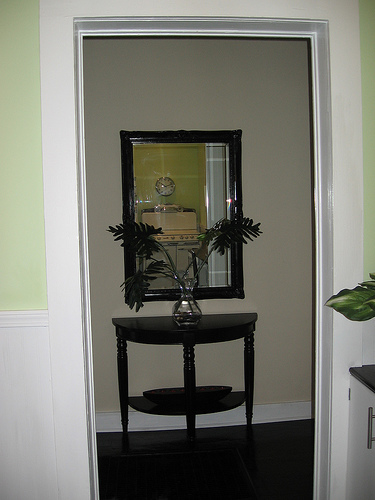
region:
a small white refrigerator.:
[343, 360, 374, 498]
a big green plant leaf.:
[323, 266, 374, 330]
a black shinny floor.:
[270, 440, 303, 483]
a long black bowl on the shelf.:
[140, 379, 237, 407]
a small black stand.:
[112, 310, 262, 453]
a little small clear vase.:
[166, 292, 212, 330]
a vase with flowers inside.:
[104, 202, 267, 327]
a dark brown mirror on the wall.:
[112, 117, 254, 308]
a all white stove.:
[138, 205, 207, 291]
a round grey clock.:
[145, 169, 184, 199]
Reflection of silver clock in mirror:
[154, 173, 178, 197]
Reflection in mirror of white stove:
[157, 204, 198, 253]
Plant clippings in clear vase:
[105, 218, 262, 327]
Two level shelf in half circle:
[111, 310, 258, 452]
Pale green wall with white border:
[6, 184, 46, 331]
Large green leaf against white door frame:
[318, 280, 371, 329]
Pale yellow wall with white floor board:
[259, 126, 310, 420]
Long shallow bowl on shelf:
[144, 383, 233, 409]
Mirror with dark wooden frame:
[114, 128, 248, 222]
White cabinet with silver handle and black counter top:
[344, 359, 374, 451]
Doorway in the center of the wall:
[69, 13, 337, 498]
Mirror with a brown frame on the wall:
[115, 127, 246, 305]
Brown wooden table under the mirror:
[109, 308, 262, 437]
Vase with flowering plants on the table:
[105, 213, 264, 329]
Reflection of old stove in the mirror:
[137, 203, 202, 294]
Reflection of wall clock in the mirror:
[150, 172, 177, 198]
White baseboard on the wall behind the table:
[94, 397, 316, 436]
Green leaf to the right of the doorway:
[323, 254, 373, 330]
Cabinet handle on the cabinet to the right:
[356, 405, 373, 456]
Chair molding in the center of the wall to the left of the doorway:
[0, 305, 51, 330]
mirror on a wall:
[110, 107, 260, 210]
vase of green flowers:
[100, 214, 250, 334]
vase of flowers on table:
[109, 210, 254, 315]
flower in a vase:
[198, 208, 260, 269]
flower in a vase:
[105, 215, 165, 251]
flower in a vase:
[120, 256, 150, 319]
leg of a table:
[226, 332, 260, 437]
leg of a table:
[178, 340, 211, 460]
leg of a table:
[111, 323, 130, 450]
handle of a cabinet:
[362, 399, 374, 454]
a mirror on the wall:
[104, 112, 255, 316]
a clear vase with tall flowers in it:
[126, 197, 256, 347]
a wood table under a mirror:
[96, 308, 266, 453]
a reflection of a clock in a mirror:
[130, 134, 222, 204]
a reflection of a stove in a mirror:
[142, 185, 210, 287]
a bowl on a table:
[135, 373, 246, 416]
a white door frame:
[64, 11, 361, 483]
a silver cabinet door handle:
[361, 403, 373, 453]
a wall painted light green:
[4, 151, 46, 314]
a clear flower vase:
[162, 267, 204, 333]